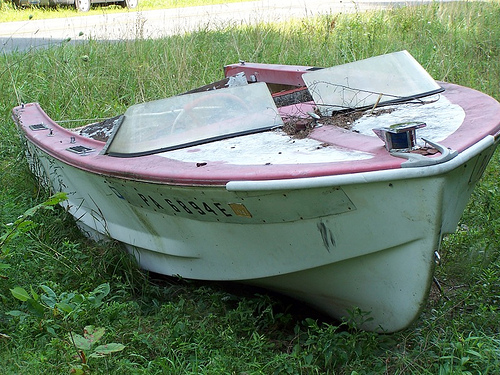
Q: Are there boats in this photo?
A: Yes, there is a boat.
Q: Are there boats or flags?
A: Yes, there is a boat.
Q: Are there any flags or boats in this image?
A: Yes, there is a boat.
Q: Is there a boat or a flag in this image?
A: Yes, there is a boat.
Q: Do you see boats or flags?
A: Yes, there is a boat.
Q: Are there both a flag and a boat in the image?
A: No, there is a boat but no flags.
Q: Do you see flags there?
A: No, there are no flags.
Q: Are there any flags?
A: No, there are no flags.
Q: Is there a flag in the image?
A: No, there are no flags.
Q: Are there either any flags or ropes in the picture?
A: No, there are no flags or ropes.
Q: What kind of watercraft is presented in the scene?
A: The watercraft is a boat.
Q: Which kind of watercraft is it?
A: The watercraft is a boat.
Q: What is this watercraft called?
A: That is a boat.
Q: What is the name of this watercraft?
A: That is a boat.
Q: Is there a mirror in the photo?
A: No, there are no mirrors.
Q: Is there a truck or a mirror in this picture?
A: No, there are no mirrors or trucks.